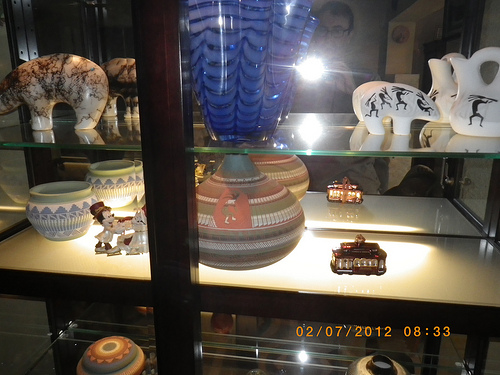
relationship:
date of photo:
[292, 315, 454, 347] [6, 6, 483, 364]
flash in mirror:
[289, 45, 341, 85] [218, 16, 480, 227]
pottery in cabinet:
[192, 155, 303, 286] [200, 149, 497, 315]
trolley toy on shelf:
[327, 233, 390, 279] [0, 178, 497, 303]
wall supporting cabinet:
[18, 2, 471, 372] [1, 0, 484, 370]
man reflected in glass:
[286, 0, 381, 192] [1, 1, 484, 372]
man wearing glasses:
[286, 0, 381, 192] [313, 22, 351, 38]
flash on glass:
[289, 49, 334, 85] [181, 9, 499, 372]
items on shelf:
[329, 41, 484, 136] [187, 100, 495, 160]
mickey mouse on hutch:
[89, 201, 125, 256] [1, 175, 493, 364]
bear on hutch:
[16, 52, 115, 151] [1, 111, 158, 155]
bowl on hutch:
[22, 180, 96, 242] [0, 127, 499, 370]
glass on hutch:
[179, 0, 309, 148] [8, 2, 491, 370]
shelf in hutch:
[187, 100, 495, 160] [8, 2, 491, 370]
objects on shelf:
[11, 20, 483, 142] [9, 95, 482, 151]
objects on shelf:
[24, 155, 389, 292] [9, 206, 484, 320]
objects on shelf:
[13, 25, 483, 130] [14, 113, 480, 153]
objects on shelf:
[24, 155, 389, 292] [22, 203, 479, 303]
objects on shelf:
[24, 155, 389, 292] [20, 195, 482, 314]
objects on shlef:
[34, 155, 387, 293] [22, 200, 482, 318]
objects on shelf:
[11, 20, 483, 142] [187, 100, 495, 160]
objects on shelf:
[11, 20, 483, 142] [12, 109, 455, 159]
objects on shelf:
[24, 155, 389, 292] [30, 227, 481, 301]